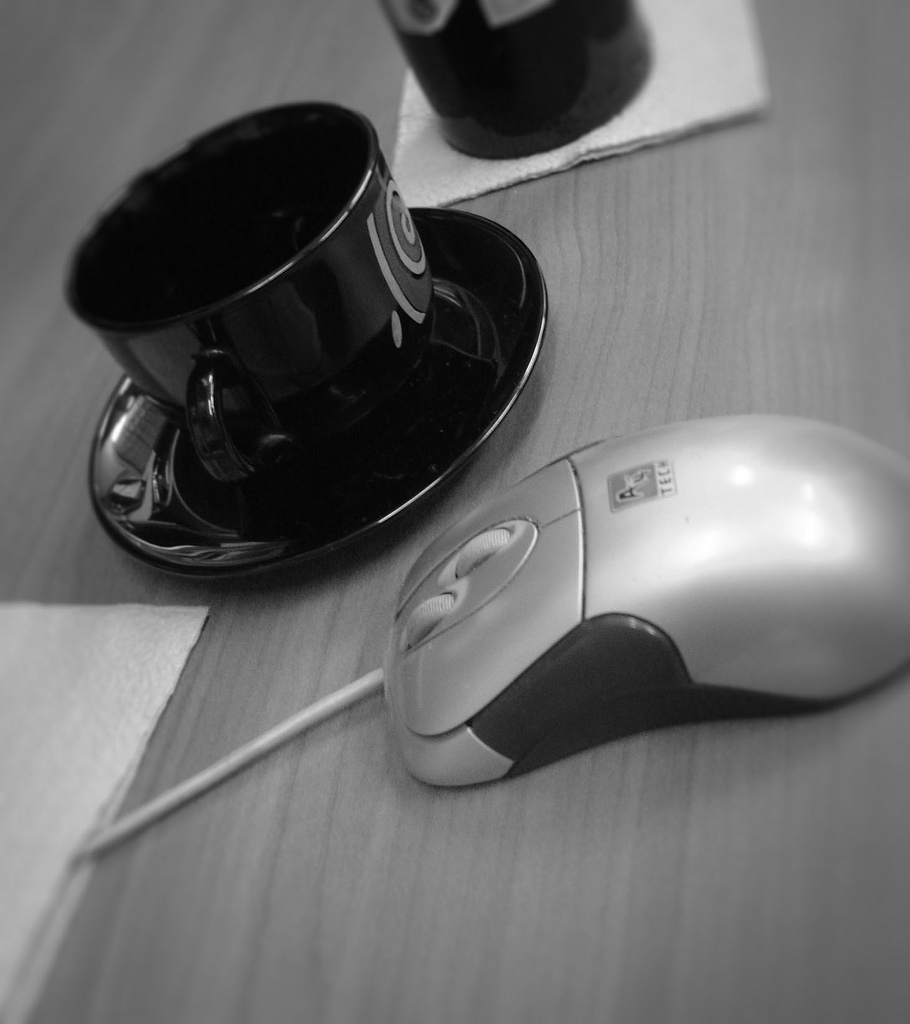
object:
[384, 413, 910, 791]
computer mouse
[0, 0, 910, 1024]
table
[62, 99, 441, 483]
cup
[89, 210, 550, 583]
saucer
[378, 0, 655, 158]
object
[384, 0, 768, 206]
napkin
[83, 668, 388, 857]
wire connector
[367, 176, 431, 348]
design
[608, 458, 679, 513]
brand name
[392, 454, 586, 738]
clicker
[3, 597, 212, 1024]
paper towel